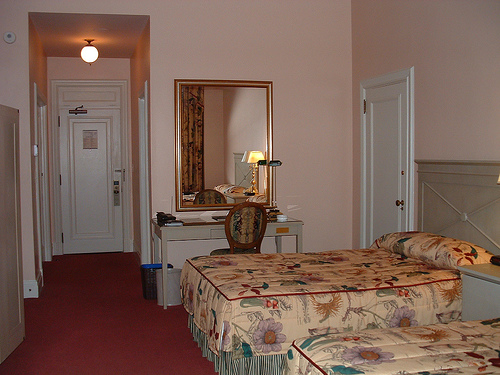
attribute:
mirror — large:
[169, 73, 282, 216]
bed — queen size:
[164, 226, 500, 375]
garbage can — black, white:
[138, 257, 171, 308]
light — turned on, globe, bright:
[76, 40, 102, 68]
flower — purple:
[460, 336, 499, 370]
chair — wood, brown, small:
[215, 195, 275, 256]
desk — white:
[144, 208, 312, 318]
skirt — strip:
[175, 316, 294, 374]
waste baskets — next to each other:
[135, 257, 188, 315]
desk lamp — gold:
[258, 156, 288, 222]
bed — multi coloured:
[178, 226, 496, 353]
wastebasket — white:
[151, 262, 187, 313]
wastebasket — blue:
[138, 257, 158, 301]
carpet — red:
[16, 241, 196, 374]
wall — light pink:
[268, 7, 359, 240]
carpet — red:
[6, 237, 208, 373]